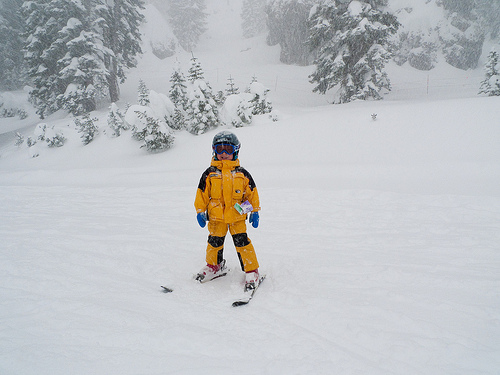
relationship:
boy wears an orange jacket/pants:
[192, 129, 262, 280] [196, 163, 263, 281]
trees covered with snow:
[0, 0, 427, 123] [296, 150, 452, 365]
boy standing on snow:
[192, 129, 262, 280] [310, 153, 450, 372]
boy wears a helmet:
[196, 130, 266, 286] [208, 129, 242, 156]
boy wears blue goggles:
[192, 129, 262, 280] [213, 143, 236, 156]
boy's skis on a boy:
[158, 268, 263, 307] [160, 130, 263, 306]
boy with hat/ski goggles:
[186, 129, 279, 308] [207, 130, 239, 162]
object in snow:
[366, 109, 384, 126] [266, 80, 496, 345]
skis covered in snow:
[158, 270, 279, 312] [33, 167, 489, 352]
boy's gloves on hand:
[194, 210, 211, 228] [188, 208, 215, 229]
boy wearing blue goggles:
[185, 130, 273, 264] [213, 143, 236, 156]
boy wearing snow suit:
[186, 126, 282, 277] [190, 150, 271, 273]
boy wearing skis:
[186, 129, 279, 308] [157, 264, 229, 295]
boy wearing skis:
[186, 129, 279, 308] [230, 269, 269, 312]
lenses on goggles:
[214, 139, 233, 154] [211, 135, 243, 159]